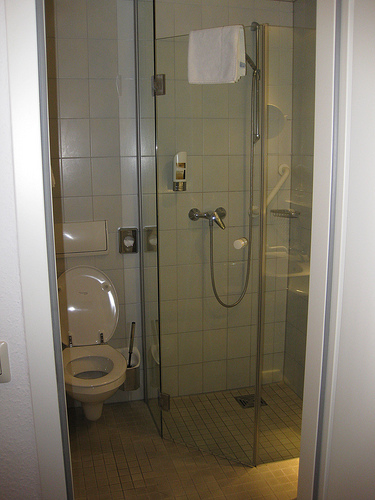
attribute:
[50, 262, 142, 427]
toilet — white, bowl 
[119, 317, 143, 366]
brush — handled, silver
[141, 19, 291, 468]
door — glass, clear, hinged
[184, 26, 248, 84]
towel — white, thrown over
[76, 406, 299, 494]
floor — lit, brown, beige, tiled, brownish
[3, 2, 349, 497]
bathroom — open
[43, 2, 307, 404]
wall — tiled, white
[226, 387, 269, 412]
drain — metal, gray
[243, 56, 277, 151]
shower head — silver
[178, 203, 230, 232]
faucet — metal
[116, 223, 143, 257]
dispenser — silver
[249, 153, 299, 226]
rail — white